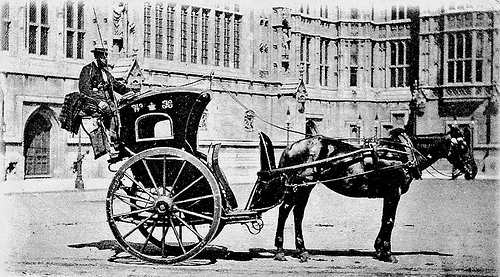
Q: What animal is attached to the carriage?
A: A horse.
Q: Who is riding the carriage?
A: A man.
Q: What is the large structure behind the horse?
A: A building.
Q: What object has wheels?
A: The carriage.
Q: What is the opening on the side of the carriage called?
A: A window.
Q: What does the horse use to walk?
A: Legs.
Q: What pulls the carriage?
A: A horse.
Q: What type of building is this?
A: Old.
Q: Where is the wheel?
A: On carriage.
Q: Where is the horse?
A: Attached to carriage.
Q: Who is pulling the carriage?
A: Horse.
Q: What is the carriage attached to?
A: Horse.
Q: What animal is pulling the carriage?
A: Horse.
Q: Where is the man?
A: Carriage.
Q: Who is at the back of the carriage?
A: A man.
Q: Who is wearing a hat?
A: A man.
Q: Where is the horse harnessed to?
A: A carriage.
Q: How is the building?
A: The building is very old.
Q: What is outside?
A: A horse and carriage.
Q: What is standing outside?
A: A carriage and horse.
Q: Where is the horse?
A: On the road.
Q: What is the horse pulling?
A: Carriage.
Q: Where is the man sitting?
A: On the carraige.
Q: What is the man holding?
A: Whip.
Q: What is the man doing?
A: Controlling the horse.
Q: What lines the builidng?
A: Windows.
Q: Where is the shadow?
A: On the ground.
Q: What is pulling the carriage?
A: A horse.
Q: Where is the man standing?
A: Back of carriage.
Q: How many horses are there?
A: One.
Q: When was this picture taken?
A: Daytime.